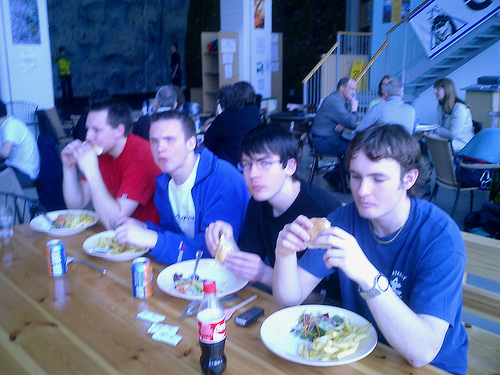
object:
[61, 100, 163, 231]
guy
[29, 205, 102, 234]
lunch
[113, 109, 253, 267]
guy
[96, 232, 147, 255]
lunch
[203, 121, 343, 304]
guy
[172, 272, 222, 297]
lunch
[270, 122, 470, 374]
guy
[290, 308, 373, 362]
lunch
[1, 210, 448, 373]
table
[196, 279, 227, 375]
bottle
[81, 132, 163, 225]
t-shirt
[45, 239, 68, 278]
can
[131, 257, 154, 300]
can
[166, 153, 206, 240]
t-shirt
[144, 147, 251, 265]
jacket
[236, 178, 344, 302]
t-shirt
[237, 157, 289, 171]
glasses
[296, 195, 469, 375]
t-shirt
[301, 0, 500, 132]
stairs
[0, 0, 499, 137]
background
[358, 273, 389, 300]
watch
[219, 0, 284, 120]
column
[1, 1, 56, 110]
column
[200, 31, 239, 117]
shelving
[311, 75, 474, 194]
people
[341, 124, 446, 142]
table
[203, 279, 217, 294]
cap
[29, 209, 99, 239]
bowl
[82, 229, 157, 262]
bowl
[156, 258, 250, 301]
bowl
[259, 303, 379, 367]
bowl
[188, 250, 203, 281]
utensil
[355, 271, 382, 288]
wrist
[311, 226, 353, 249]
fingers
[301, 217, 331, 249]
bread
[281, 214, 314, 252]
fingers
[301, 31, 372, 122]
railing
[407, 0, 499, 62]
banner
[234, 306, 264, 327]
phone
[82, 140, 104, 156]
sandwich